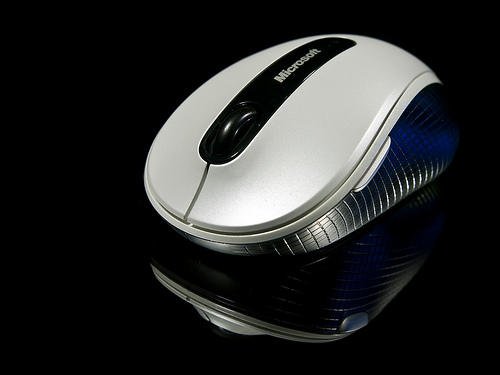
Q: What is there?
A: Mouse.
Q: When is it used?
A: For Computers.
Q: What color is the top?
A: Silver.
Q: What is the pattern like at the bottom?
A: Grid.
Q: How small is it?
A: Relatively small.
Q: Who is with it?
A: Nobody.